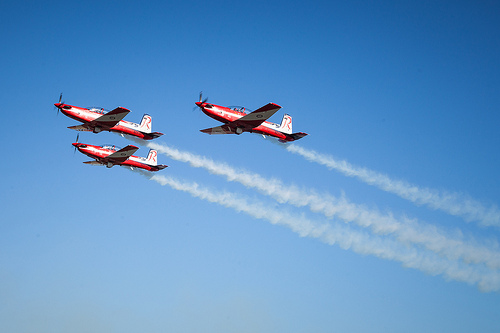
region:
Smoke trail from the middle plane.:
[140, 136, 499, 272]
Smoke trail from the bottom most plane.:
[122, 161, 498, 296]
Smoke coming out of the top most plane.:
[272, 134, 498, 231]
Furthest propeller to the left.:
[52, 88, 65, 117]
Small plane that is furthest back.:
[192, 91, 309, 146]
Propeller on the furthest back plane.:
[190, 87, 208, 114]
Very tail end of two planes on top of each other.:
[137, 109, 164, 174]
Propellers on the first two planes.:
[52, 94, 85, 159]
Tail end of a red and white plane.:
[282, 111, 293, 135]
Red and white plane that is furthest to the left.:
[53, 92, 163, 142]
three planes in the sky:
[24, 61, 325, 198]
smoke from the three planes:
[304, 144, 495, 303]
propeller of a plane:
[189, 85, 210, 115]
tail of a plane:
[139, 108, 156, 138]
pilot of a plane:
[223, 100, 256, 115]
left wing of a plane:
[101, 141, 147, 160]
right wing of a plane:
[196, 118, 236, 136]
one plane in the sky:
[182, 84, 310, 151]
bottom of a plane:
[253, 122, 290, 141]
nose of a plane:
[49, 99, 65, 112]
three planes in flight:
[42, 80, 316, 181]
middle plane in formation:
[42, 89, 162, 144]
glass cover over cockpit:
[224, 99, 253, 119]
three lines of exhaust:
[270, 160, 389, 245]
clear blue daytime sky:
[318, 19, 443, 115]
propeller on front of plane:
[183, 84, 210, 116]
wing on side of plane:
[93, 102, 131, 135]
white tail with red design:
[268, 107, 300, 147]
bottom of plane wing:
[236, 108, 280, 130]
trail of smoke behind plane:
[162, 172, 278, 219]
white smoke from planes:
[318, 130, 424, 255]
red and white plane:
[193, 72, 294, 194]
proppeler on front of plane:
[168, 66, 215, 134]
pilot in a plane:
[88, 90, 105, 124]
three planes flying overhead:
[0, 65, 319, 190]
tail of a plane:
[263, 108, 314, 166]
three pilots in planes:
[49, 52, 254, 216]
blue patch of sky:
[351, 37, 452, 114]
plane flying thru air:
[193, 85, 293, 185]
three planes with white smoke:
[55, 87, 394, 276]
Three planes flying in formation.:
[16, 27, 443, 295]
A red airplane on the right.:
[189, 79, 319, 152]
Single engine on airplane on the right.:
[191, 87, 211, 112]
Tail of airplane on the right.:
[275, 104, 307, 152]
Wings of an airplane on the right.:
[191, 90, 277, 149]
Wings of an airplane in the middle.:
[56, 92, 131, 133]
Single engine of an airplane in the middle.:
[43, 80, 77, 127]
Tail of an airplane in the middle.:
[134, 114, 161, 139]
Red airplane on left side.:
[68, 132, 179, 178]